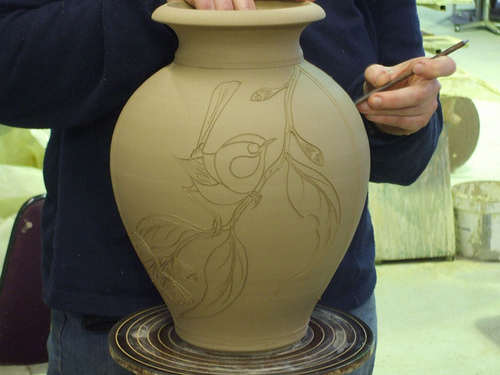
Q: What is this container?
A: Pot.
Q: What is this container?
A: Pot.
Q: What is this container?
A: Pot.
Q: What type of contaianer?
A: Pot.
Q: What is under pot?
A: Table.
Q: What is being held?
A: Etching tool.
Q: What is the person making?
A: Vase.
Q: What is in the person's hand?
A: Carving knife.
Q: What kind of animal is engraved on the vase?
A: Bird.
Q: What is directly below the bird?
A: Large leaf.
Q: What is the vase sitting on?
A: Pedastal.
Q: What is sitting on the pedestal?
A: Vase.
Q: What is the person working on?
A: Vase.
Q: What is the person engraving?
A: Vase.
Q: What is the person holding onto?
A: Top of vase.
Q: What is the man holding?
A: An engraving tool.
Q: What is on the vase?
A: A bird.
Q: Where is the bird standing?
A: On a branch.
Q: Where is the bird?
A: On the vase.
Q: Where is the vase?
A: On the turn table.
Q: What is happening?
A: Pottery.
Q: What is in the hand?
A: An etch stick.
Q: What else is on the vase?
A: Leaves.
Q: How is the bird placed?
A: Etched.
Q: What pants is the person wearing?
A: Blue jeans.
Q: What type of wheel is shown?
A: Potter's wheel.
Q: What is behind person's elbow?
A: Part of a table.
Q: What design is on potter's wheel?
A: Rings.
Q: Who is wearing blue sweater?
A: Potter.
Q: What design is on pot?
A: Flower with leaves.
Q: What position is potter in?
A: Standing.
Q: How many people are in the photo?
A: One.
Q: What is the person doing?
A: Carving designs into pottery.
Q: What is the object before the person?
A: Pottery vase.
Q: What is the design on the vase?
A: Flowers.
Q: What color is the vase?
A: Tan.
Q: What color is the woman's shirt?
A: Blue.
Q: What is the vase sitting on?
A: Table.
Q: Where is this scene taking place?
A: At pottery class.